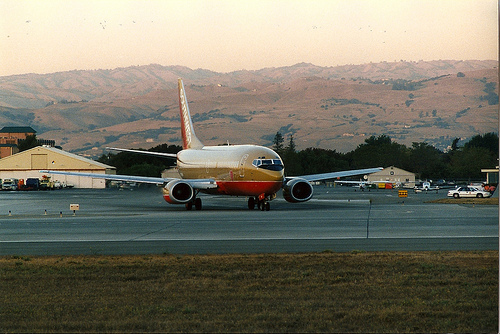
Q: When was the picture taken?
A: Daytime.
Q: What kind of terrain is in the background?
A: Mountains.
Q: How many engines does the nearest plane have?
A: Two.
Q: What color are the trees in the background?
A: Green.